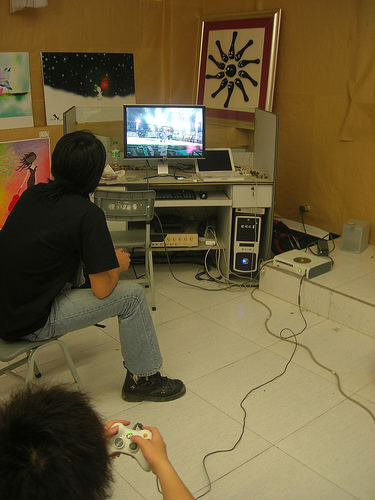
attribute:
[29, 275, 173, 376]
jean — blue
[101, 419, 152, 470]
controller — xbox controller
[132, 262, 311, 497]
cord — gray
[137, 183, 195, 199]
keyboard — black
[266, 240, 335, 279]
console — gray, white, xbox console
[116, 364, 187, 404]
shoe — black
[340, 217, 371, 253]
speaker — gray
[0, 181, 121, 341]
shirt — black, short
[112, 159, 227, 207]
keyboard — black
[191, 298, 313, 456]
floor — white, tiled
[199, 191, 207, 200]
mouse — black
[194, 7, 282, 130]
artwork —  Four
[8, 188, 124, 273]
shirt — black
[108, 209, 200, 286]
chair — grey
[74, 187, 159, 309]
chair — plastic, gray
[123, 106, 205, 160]
monitor —   on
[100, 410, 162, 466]
game controller — white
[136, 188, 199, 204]
keyboard — black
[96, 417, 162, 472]
controller — white, gray, xbox controller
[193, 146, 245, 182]
laptop — white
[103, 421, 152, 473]
controller — white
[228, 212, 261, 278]
modem —  for Desktop computer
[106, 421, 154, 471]
game controller — white, gray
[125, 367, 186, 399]
sneaker —  BLACK 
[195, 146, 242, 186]
white laptop —  white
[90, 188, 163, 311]
chair — gray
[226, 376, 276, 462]
cord — gray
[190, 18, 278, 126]
framed art — black, red, white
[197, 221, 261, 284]
cords — multiple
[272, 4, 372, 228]
paper — Brown